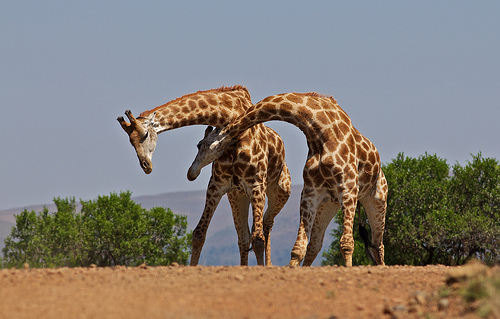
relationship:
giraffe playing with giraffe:
[185, 89, 390, 274] [117, 86, 289, 265]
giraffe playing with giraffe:
[183, 92, 407, 264] [117, 86, 289, 265]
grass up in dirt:
[446, 274, 491, 306] [30, 272, 494, 315]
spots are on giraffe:
[326, 142, 357, 173] [185, 89, 390, 274]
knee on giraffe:
[247, 220, 268, 253] [117, 86, 289, 265]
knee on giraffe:
[340, 232, 359, 256] [185, 89, 390, 274]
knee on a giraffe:
[186, 226, 207, 246] [117, 86, 289, 265]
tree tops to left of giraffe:
[4, 190, 191, 266] [188, 79, 404, 264]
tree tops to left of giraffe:
[4, 190, 191, 266] [117, 86, 289, 265]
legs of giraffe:
[292, 201, 392, 266] [185, 89, 390, 274]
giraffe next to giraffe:
[117, 86, 289, 265] [185, 89, 390, 274]